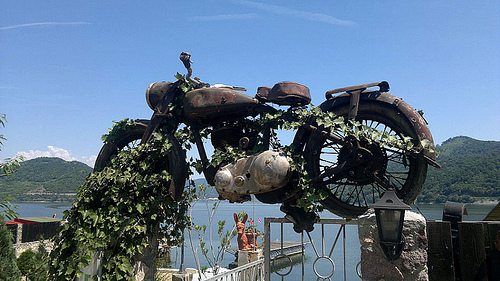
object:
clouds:
[236, 1, 358, 30]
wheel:
[333, 139, 389, 187]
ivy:
[41, 116, 219, 281]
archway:
[46, 49, 443, 281]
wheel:
[300, 102, 429, 220]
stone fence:
[355, 207, 430, 281]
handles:
[175, 50, 197, 80]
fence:
[423, 220, 498, 281]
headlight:
[143, 79, 181, 112]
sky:
[0, 0, 499, 181]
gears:
[207, 118, 274, 155]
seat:
[252, 80, 313, 108]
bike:
[90, 49, 436, 221]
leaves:
[113, 173, 131, 188]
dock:
[3, 196, 498, 279]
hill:
[0, 155, 94, 203]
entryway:
[49, 50, 444, 280]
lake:
[0, 193, 499, 280]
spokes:
[337, 180, 349, 200]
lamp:
[366, 187, 412, 262]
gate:
[259, 215, 364, 279]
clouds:
[8, 142, 98, 168]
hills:
[322, 135, 499, 205]